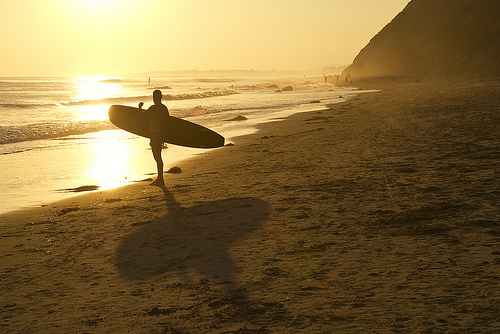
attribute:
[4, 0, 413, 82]
clouds — white 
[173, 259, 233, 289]
sand — wet 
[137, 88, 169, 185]
man — posing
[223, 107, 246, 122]
rock — multiple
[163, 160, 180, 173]
rock — multiple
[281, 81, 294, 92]
rock — multiple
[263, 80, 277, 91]
rock — multiple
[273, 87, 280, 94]
rock — multiple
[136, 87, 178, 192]
surfer — shirtless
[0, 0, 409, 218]
sky — blue 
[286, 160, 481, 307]
sand — wet 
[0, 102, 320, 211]
sand — wet 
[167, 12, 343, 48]
sky — blue 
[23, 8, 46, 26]
clouds — white 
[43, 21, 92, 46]
clouds — white 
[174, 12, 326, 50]
sky — blue 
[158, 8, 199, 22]
clouds — white 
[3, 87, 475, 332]
beach — wet 